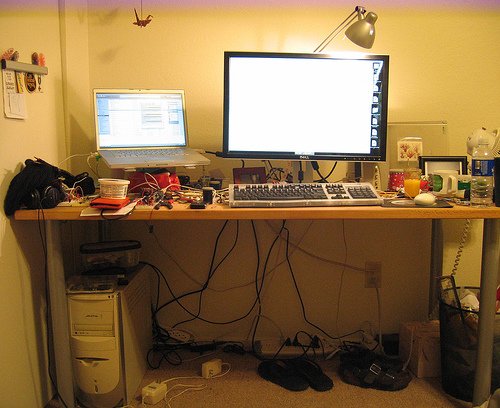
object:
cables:
[133, 363, 231, 408]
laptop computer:
[92, 88, 210, 172]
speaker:
[345, 161, 381, 190]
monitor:
[228, 56, 384, 155]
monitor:
[95, 93, 186, 148]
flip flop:
[258, 360, 309, 391]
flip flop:
[288, 356, 333, 391]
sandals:
[338, 349, 412, 391]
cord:
[263, 219, 375, 273]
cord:
[251, 219, 292, 360]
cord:
[146, 219, 239, 368]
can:
[435, 275, 499, 403]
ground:
[286, 392, 391, 407]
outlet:
[364, 261, 381, 288]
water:
[474, 178, 488, 202]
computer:
[221, 51, 389, 184]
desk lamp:
[313, 5, 378, 52]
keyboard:
[228, 183, 383, 208]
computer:
[66, 263, 155, 407]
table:
[12, 180, 500, 219]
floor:
[129, 345, 469, 408]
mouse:
[414, 191, 435, 204]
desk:
[13, 179, 499, 407]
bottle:
[470, 138, 495, 209]